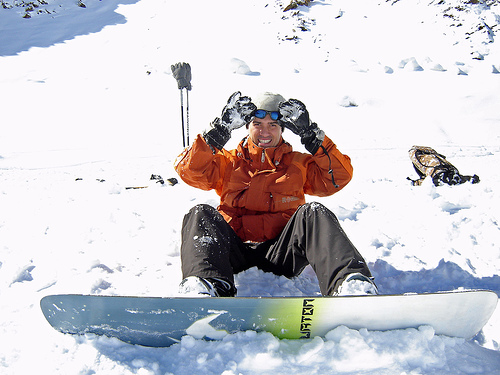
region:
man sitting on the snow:
[42, 77, 498, 357]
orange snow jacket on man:
[177, 120, 352, 230]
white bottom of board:
[313, 291, 495, 353]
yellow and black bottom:
[275, 298, 322, 350]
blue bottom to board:
[49, 299, 271, 352]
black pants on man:
[184, 208, 359, 291]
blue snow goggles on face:
[254, 109, 281, 120]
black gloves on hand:
[197, 97, 258, 154]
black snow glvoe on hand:
[283, 97, 321, 142]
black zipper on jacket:
[327, 155, 345, 195]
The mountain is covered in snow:
[5, 18, 495, 362]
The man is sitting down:
[140, 73, 398, 286]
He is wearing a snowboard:
[40, 69, 498, 354]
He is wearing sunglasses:
[212, 93, 307, 126]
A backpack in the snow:
[394, 135, 477, 195]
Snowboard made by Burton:
[292, 292, 326, 347]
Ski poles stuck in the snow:
[163, 53, 204, 165]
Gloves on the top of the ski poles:
[162, 50, 204, 90]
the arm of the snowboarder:
[177, 136, 231, 188]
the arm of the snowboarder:
[295, 134, 354, 196]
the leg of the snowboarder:
[181, 208, 244, 293]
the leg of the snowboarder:
[264, 202, 366, 288]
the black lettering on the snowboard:
[297, 293, 314, 345]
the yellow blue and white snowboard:
[42, 289, 497, 347]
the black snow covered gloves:
[202, 91, 252, 146]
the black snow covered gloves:
[278, 98, 317, 148]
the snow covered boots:
[176, 275, 219, 302]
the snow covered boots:
[331, 273, 376, 299]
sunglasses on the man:
[245, 107, 287, 120]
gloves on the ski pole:
[168, 61, 192, 96]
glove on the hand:
[215, 92, 255, 131]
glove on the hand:
[276, 97, 318, 138]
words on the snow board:
[291, 300, 316, 340]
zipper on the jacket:
[258, 152, 265, 165]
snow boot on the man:
[161, 268, 228, 298]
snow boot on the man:
[334, 272, 384, 302]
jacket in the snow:
[391, 132, 477, 189]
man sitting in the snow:
[41, 85, 491, 348]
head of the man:
[212, 90, 314, 163]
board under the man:
[54, 261, 491, 358]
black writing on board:
[276, 294, 324, 349]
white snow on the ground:
[36, 214, 153, 283]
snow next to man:
[63, 222, 165, 288]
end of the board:
[28, 267, 105, 352]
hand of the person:
[273, 87, 327, 150]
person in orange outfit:
[164, 80, 353, 255]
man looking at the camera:
[198, 79, 339, 191]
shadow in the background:
[32, 4, 136, 67]